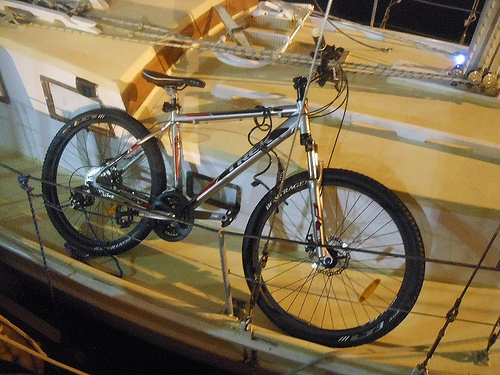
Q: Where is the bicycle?
A: On the boat.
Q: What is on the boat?
A: A bicycle.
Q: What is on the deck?
A: A bicycle.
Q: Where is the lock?
A: On the bicycle.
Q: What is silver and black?
A: Bike.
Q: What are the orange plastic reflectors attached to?
A: The spokes.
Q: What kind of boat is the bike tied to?
A: Sailboat.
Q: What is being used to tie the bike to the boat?
A: Blue striped rope.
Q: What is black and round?
A: Tires.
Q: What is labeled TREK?
A: The bike.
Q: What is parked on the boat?
A: A bike.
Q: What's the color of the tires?
A: Black.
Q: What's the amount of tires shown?
A: Two.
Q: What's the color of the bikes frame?
A: Silver.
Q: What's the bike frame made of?
A: Metal.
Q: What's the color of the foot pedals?
A: Black.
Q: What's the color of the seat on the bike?
A: Black.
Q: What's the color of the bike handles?
A: Black.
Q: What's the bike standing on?
A: Boat.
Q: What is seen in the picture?
A: Bicycle.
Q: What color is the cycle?
A: Grey and black.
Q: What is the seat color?
A: Black.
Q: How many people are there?
A: No one.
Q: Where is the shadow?
A: Down in the base.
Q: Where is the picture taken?
A: On a boat.